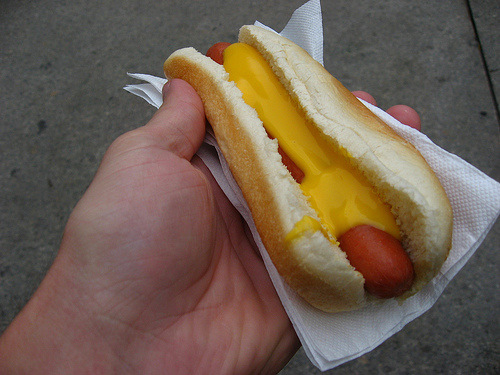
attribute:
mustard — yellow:
[216, 45, 407, 259]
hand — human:
[0, 27, 435, 373]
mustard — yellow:
[222, 41, 403, 246]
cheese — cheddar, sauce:
[254, 91, 369, 241]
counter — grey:
[6, 44, 124, 136]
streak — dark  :
[453, 2, 496, 121]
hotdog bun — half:
[165, 31, 460, 306]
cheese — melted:
[221, 33, 406, 261]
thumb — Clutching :
[103, 78, 212, 156]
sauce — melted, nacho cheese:
[219, 40, 398, 250]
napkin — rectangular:
[117, 40, 495, 356]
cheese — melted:
[234, 47, 384, 234]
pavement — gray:
[0, 8, 145, 149]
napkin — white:
[365, 101, 485, 326]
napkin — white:
[452, 148, 499, 230]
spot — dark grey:
[31, 113, 54, 141]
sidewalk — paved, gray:
[26, 21, 487, 153]